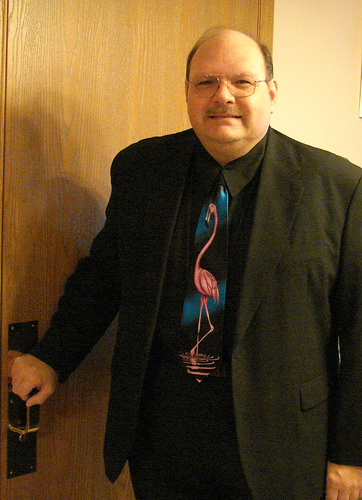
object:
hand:
[4, 348, 59, 410]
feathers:
[204, 275, 212, 288]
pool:
[178, 354, 221, 387]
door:
[0, 0, 275, 495]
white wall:
[276, 5, 356, 151]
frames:
[193, 75, 257, 96]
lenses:
[196, 72, 218, 97]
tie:
[177, 171, 228, 386]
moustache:
[206, 105, 243, 115]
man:
[10, 23, 362, 499]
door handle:
[5, 316, 45, 480]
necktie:
[178, 176, 229, 384]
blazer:
[27, 123, 362, 500]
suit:
[29, 120, 362, 500]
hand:
[12, 350, 58, 408]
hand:
[325, 459, 362, 499]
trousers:
[126, 361, 252, 498]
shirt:
[150, 129, 271, 456]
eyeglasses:
[191, 74, 257, 98]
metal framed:
[184, 74, 267, 96]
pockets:
[298, 378, 332, 433]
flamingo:
[189, 201, 221, 357]